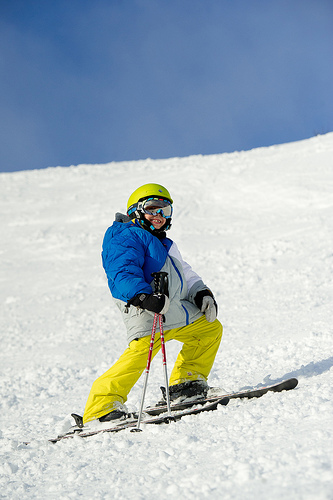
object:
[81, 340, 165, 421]
pants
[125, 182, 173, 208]
helmet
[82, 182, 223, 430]
boy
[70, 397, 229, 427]
skis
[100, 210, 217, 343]
jacket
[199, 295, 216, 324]
glove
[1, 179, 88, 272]
snow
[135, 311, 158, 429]
poles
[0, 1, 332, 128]
sky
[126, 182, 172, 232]
head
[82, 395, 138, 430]
feet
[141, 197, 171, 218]
goggles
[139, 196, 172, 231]
face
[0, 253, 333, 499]
ground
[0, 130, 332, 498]
hill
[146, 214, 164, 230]
smile